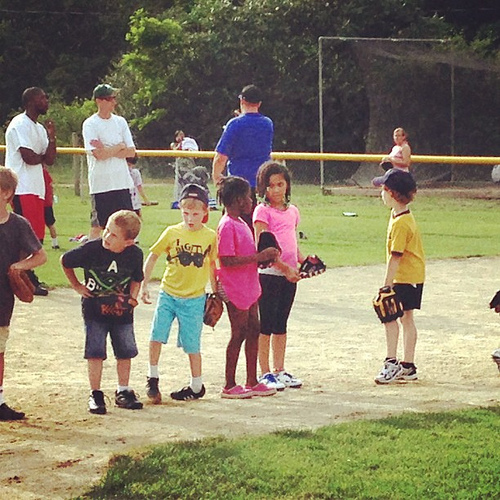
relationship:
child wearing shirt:
[211, 173, 280, 401] [214, 215, 262, 311]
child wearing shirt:
[249, 158, 303, 391] [251, 203, 300, 270]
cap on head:
[242, 78, 281, 108] [239, 82, 266, 114]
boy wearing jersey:
[150, 190, 220, 425] [150, 222, 217, 296]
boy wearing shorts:
[150, 190, 220, 425] [149, 287, 205, 352]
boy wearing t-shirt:
[60, 211, 145, 414] [62, 237, 145, 325]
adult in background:
[377, 127, 412, 176] [15, 16, 483, 294]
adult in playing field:
[210, 84, 275, 210] [4, 177, 484, 491]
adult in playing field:
[7, 85, 50, 296] [4, 177, 484, 491]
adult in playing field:
[83, 82, 137, 238] [4, 177, 484, 491]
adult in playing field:
[377, 127, 412, 176] [4, 177, 484, 491]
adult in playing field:
[169, 128, 199, 201] [4, 177, 484, 491]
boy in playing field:
[60, 211, 145, 414] [4, 177, 484, 491]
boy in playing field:
[150, 190, 220, 425] [4, 177, 484, 491]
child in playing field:
[211, 173, 280, 401] [4, 177, 484, 491]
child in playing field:
[249, 158, 303, 391] [4, 177, 484, 491]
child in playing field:
[373, 164, 428, 384] [4, 177, 484, 491]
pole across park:
[303, 144, 498, 176] [4, 2, 499, 342]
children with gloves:
[4, 162, 425, 422] [7, 267, 48, 302]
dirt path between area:
[0, 253, 499, 495] [97, 414, 497, 497]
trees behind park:
[10, 1, 499, 183] [3, 178, 495, 498]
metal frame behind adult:
[316, 31, 478, 186] [377, 127, 412, 176]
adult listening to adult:
[83, 82, 137, 238] [210, 84, 275, 210]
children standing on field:
[0, 167, 46, 417] [0, 183, 499, 497]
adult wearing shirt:
[80, 82, 137, 229] [77, 113, 134, 193]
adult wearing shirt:
[3, 85, 49, 296] [3, 113, 48, 197]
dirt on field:
[2, 251, 497, 496] [0, 183, 499, 497]